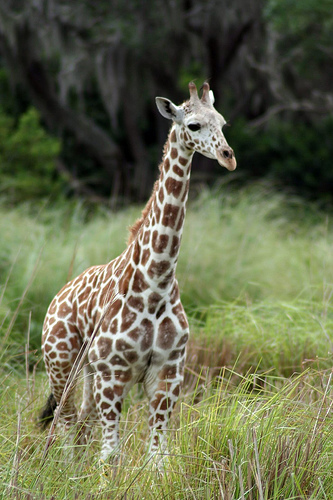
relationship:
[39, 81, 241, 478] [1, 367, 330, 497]
giraffe in field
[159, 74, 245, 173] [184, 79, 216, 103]
head has horns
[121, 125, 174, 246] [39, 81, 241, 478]
mane on giraffe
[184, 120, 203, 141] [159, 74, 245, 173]
eye on head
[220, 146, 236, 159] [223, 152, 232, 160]
nose has nostrils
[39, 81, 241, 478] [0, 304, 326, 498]
giraffe on grass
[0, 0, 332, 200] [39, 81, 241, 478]
trees behind giraffe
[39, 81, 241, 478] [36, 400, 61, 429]
giraffe has tail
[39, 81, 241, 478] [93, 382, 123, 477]
giraffe has leg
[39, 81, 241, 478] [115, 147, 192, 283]
giraffe has neck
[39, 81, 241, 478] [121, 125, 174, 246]
giraffe has mane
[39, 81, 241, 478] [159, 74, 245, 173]
giraffe has head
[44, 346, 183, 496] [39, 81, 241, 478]
four legs of giraffe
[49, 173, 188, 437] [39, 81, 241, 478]
spots on giraffe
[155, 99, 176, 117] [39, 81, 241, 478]
ear of giraffe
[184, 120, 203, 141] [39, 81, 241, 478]
eye of giraffe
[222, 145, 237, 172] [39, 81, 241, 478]
nose of giraffe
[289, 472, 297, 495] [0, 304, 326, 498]
single blade of grass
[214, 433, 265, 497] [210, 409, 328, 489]
several blades of brown grass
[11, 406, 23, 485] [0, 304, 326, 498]
yellow strand of grass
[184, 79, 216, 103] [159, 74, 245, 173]
horns on head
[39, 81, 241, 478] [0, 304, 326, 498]
giraffe in grass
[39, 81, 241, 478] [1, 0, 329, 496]
giraffe in wilderness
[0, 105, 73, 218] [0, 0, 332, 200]
green bush near trees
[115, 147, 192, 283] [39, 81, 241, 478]
neck of giraffe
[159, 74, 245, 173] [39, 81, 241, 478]
head of giraffe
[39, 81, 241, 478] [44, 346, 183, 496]
giraffe has four legs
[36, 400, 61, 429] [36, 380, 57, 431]
tail has tail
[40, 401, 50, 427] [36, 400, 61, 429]
hair on tail